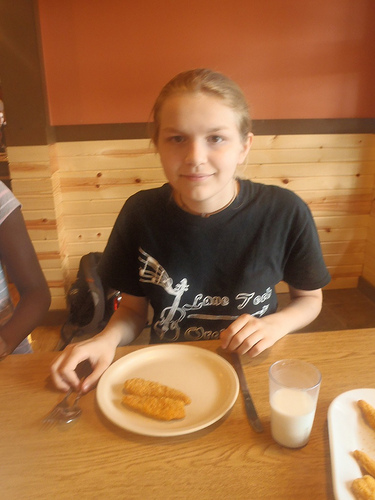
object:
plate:
[92, 340, 244, 444]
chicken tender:
[117, 390, 189, 426]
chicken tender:
[117, 375, 195, 407]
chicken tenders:
[117, 375, 195, 425]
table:
[1, 327, 373, 499]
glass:
[264, 354, 325, 453]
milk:
[265, 382, 320, 453]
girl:
[45, 65, 331, 395]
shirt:
[92, 176, 333, 347]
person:
[1, 172, 57, 365]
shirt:
[1, 176, 32, 354]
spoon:
[49, 373, 91, 429]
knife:
[223, 344, 267, 439]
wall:
[1, 131, 375, 309]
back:
[2, 2, 374, 331]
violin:
[148, 276, 193, 344]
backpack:
[60, 251, 116, 344]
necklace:
[178, 183, 235, 217]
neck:
[169, 177, 247, 215]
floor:
[31, 284, 374, 332]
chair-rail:
[1, 113, 375, 151]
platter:
[324, 385, 374, 498]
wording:
[180, 285, 275, 343]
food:
[116, 373, 374, 500]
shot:
[2, 2, 373, 499]